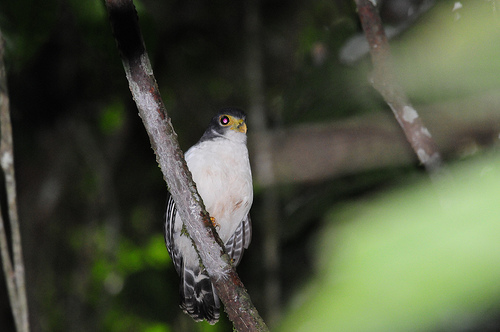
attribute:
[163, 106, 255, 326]
bird — small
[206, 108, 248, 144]
head — small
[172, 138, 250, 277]
feathers — white, gray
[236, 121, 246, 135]
peck — orange, yellow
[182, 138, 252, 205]
breast — white